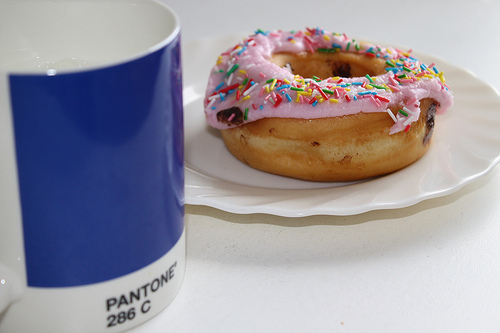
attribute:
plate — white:
[178, 52, 499, 219]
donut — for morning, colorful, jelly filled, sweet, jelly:
[202, 25, 454, 185]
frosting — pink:
[202, 26, 452, 137]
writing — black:
[97, 259, 177, 329]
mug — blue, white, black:
[0, 0, 188, 329]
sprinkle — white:
[241, 82, 259, 96]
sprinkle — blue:
[285, 91, 294, 101]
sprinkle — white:
[386, 105, 399, 124]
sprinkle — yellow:
[297, 88, 313, 98]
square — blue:
[8, 21, 182, 288]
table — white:
[101, 0, 499, 332]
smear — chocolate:
[215, 101, 244, 126]